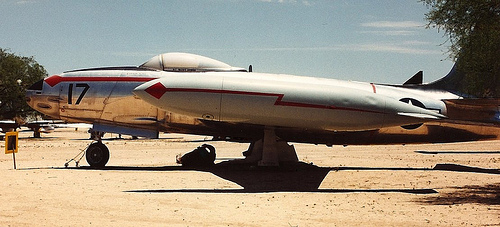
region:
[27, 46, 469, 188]
the plane is white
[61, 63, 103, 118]
the text is black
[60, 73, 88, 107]
the number is 17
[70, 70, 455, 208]
the plane is on the ground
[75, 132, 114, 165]
the tires are black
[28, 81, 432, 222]
the plane is on sand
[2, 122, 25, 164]
the sign is yellow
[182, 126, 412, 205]
the plane casts a large shadow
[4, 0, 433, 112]
the skies are clear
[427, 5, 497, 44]
vegetation behind the plane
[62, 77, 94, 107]
Black number seventeen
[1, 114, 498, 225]
Ground covered in sand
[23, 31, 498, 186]
Airplane landed on sand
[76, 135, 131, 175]
Front wheel of the plane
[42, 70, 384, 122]
Red stripes along side of plane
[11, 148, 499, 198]
Shadow of plane on the ground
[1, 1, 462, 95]
Sky with very few clouds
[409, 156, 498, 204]
Shadow of a tree on the ground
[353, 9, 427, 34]
One of few clouds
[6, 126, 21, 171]
Yellow and black sign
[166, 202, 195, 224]
a rock on ground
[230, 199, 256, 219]
a rock on ground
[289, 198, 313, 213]
a rock on ground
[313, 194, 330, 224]
a rock on ground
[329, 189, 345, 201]
a rock on ground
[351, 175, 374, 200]
a rock on ground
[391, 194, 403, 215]
a rock on ground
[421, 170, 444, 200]
a rock on ground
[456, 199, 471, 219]
a rock on ground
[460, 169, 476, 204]
a rock on ground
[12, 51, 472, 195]
jet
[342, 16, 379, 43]
white snow on hill side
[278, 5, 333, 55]
white snow on hill side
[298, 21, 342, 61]
white snow on hill side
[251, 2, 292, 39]
white snow on hill side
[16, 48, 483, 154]
silver plane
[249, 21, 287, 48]
white clouds in blue sky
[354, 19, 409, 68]
white clouds in blue sky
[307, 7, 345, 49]
white clouds in blue sky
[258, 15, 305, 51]
white clouds in blue sky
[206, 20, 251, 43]
white clouds in blue sky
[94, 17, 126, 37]
white clouds in blue sky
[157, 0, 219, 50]
white clouds in blue sky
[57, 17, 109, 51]
white clouds in blue sky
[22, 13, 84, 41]
white clouds in blue sky